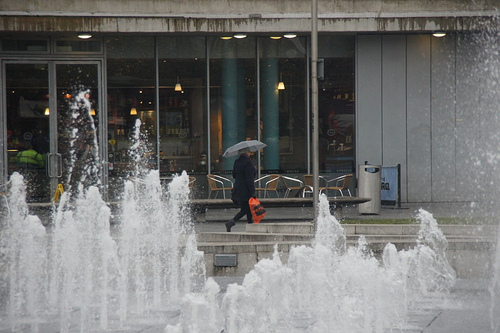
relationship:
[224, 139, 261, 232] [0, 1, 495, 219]
woman passing in front building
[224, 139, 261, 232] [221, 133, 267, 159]
woman holds an umbrella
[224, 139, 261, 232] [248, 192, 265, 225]
woman holds bag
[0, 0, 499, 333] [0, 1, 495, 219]
water in front of building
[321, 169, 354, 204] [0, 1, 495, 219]
chair in front of building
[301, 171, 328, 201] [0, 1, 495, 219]
chair in front of building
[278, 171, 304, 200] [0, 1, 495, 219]
chair in front of building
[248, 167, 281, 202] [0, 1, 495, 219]
chair in front of building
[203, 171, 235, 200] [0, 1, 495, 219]
chair in front of building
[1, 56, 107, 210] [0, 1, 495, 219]
door of building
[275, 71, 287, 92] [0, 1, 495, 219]
lamp inside building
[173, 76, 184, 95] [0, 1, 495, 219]
lamp inside building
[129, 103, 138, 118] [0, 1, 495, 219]
lamp inside building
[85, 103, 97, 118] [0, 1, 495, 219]
lamp inside building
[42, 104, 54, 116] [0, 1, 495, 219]
lamp inside building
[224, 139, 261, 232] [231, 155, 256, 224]
woman wears an outfit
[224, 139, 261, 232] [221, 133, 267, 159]
woman has an umbrella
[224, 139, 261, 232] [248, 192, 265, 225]
woman carries bag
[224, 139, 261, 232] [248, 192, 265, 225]
woman holding bag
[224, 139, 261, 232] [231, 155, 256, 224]
woman has outfit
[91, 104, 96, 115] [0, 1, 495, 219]
lamp inside building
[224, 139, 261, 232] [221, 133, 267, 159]
woman holding an umbrella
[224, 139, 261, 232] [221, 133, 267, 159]
woman carrying an umbrella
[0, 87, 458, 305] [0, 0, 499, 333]
water gushes from water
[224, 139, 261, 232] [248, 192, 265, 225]
woman carries a bag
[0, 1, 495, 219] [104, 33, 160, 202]
building has window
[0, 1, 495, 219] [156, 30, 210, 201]
building has window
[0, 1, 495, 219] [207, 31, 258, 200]
building has window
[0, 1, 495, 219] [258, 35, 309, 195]
building has window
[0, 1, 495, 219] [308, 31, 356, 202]
building has window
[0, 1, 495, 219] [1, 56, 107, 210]
building has door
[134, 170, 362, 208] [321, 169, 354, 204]
row has chair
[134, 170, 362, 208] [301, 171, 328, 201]
row has chair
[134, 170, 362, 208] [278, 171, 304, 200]
row has chair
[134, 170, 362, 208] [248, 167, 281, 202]
row has chair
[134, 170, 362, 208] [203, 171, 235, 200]
row has chair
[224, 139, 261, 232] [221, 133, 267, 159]
woman carries an umbrella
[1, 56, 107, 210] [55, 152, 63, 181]
door has handle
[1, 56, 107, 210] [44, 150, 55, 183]
door has handle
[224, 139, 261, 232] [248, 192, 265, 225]
woman carrying a bag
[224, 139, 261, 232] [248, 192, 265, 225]
woman with bag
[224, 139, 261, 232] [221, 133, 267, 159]
woman with umbrella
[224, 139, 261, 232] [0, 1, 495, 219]
woman in front of building